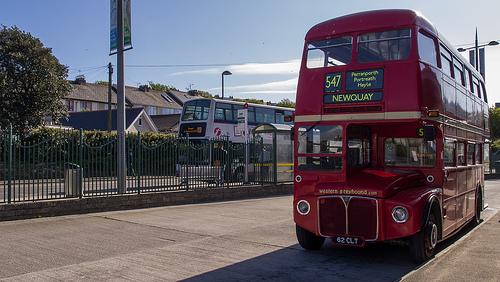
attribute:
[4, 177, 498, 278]
street — grey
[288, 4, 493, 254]
bus — red, double decker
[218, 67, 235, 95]
street light — tall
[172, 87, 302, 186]
bus — white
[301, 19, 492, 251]
bus — red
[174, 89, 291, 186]
bus — white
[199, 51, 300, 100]
clouds — white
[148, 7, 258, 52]
sky — blue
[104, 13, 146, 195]
pole — metal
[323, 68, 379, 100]
writing — yellow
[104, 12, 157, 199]
pole — tall, metal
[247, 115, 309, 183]
bus stop — clear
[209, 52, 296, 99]
clouds — white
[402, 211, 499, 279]
sidewalk — cement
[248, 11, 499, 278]
bus — red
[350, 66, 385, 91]
lights — yellow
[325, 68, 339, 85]
lights — yellow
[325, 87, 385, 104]
lights — yellow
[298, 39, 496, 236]
bus — double decker, white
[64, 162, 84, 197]
trash can — silver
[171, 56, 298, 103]
clouds — white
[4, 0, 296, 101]
sky — blue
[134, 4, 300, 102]
sky — blue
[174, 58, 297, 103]
could — white